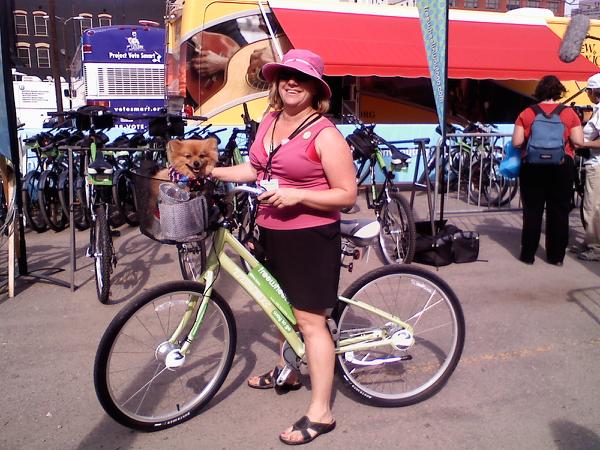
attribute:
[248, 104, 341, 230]
shirt — pink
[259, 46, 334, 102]
hat — carnelian pink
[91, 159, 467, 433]
bike — green-yellow, lime green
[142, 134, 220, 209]
dog — brown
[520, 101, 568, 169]
backpack — blue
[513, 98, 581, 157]
shirt — red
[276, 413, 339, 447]
sandal — brown, strapped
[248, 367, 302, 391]
sandal — brown, strapped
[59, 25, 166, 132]
bus — blue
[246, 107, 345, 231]
top — pink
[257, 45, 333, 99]
hat — pink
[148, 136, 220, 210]
dog — brown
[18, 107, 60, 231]
bike — parked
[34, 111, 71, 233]
bike — parked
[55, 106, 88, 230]
bike — parked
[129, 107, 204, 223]
bike — parked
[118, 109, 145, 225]
bike — parked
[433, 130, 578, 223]
barrier — gray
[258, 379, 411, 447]
sandal — brown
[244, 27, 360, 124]
hat — pink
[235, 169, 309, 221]
tag — name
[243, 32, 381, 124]
hat — pink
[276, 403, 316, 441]
sandal — black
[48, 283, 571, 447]
spot — parking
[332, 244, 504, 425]
wheel — back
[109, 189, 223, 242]
basket — bicycle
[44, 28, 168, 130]
bus — blue, white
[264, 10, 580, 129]
awning — red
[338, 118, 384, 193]
bag — black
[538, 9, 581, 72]
mic — news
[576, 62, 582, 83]
hat — white